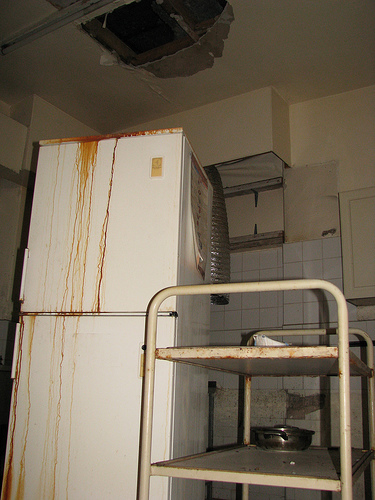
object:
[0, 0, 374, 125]
ceiling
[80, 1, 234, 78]
hole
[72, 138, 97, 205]
rust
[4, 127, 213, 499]
fridge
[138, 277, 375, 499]
shelves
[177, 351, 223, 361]
rust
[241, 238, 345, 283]
wall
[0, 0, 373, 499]
room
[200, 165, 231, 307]
ducting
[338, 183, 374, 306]
cabinet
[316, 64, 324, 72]
part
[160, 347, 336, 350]
edge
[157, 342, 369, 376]
shelf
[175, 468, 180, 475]
part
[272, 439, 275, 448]
part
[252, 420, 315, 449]
hotpot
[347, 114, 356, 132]
part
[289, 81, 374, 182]
wall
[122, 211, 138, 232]
part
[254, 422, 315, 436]
lid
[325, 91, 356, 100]
edge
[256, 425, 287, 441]
handle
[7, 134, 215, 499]
freezer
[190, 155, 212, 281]
paper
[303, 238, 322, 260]
tile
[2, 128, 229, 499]
refrigerator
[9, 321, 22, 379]
handle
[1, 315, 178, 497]
door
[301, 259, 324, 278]
tile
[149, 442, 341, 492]
shelf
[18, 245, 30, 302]
handle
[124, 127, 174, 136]
edge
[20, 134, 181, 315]
door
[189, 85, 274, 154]
wall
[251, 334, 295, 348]
paper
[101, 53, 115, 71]
spot